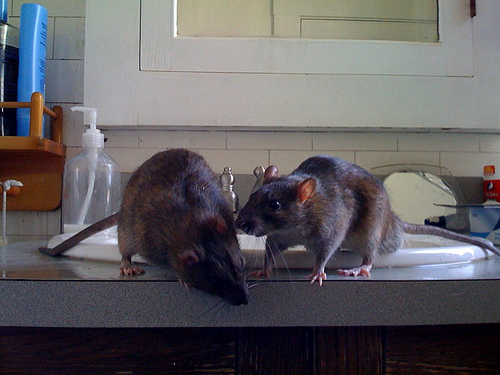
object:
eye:
[265, 197, 283, 213]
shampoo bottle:
[15, 2, 49, 139]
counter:
[0, 235, 500, 327]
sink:
[45, 232, 494, 271]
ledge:
[0, 277, 500, 329]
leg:
[345, 230, 381, 266]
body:
[249, 153, 404, 288]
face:
[233, 177, 299, 239]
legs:
[307, 236, 341, 275]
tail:
[35, 211, 119, 259]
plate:
[365, 161, 470, 236]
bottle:
[59, 106, 122, 234]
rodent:
[37, 145, 256, 322]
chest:
[80, 0, 500, 134]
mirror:
[369, 161, 468, 234]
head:
[231, 163, 317, 237]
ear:
[295, 175, 317, 207]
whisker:
[195, 299, 228, 329]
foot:
[114, 261, 148, 277]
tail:
[395, 216, 499, 257]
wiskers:
[247, 230, 296, 295]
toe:
[317, 274, 323, 287]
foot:
[300, 267, 329, 287]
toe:
[361, 268, 370, 278]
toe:
[131, 268, 141, 276]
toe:
[308, 273, 318, 286]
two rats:
[37, 145, 499, 318]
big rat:
[233, 153, 499, 287]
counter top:
[0, 232, 500, 283]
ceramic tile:
[477, 132, 499, 153]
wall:
[0, 0, 500, 244]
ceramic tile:
[139, 129, 227, 149]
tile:
[268, 150, 354, 175]